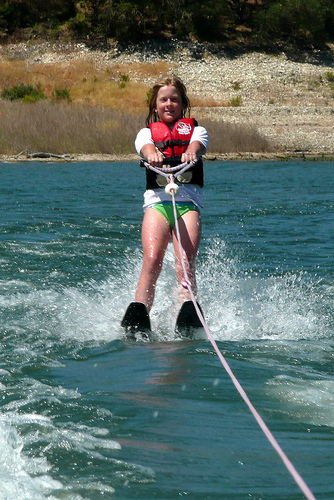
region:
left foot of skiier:
[170, 282, 222, 339]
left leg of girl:
[170, 253, 209, 315]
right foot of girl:
[108, 288, 178, 339]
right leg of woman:
[129, 244, 154, 344]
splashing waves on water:
[205, 249, 321, 337]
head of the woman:
[127, 68, 204, 119]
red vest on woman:
[140, 118, 196, 159]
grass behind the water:
[17, 95, 130, 155]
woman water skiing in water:
[98, 83, 231, 282]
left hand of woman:
[177, 143, 209, 185]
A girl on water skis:
[95, 69, 237, 351]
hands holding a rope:
[141, 146, 194, 220]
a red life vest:
[145, 118, 206, 182]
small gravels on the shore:
[210, 52, 278, 83]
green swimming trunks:
[144, 198, 199, 229]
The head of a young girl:
[152, 80, 195, 119]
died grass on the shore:
[14, 97, 114, 150]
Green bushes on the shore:
[10, 84, 72, 109]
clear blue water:
[136, 350, 234, 426]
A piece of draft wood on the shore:
[21, 150, 83, 163]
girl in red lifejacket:
[133, 75, 209, 178]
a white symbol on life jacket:
[173, 119, 193, 139]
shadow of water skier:
[112, 330, 209, 497]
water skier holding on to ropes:
[144, 77, 222, 353]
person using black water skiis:
[117, 280, 214, 343]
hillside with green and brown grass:
[5, 42, 129, 103]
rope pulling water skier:
[167, 196, 283, 448]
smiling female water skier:
[135, 68, 216, 256]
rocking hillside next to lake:
[195, 47, 320, 116]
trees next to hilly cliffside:
[47, 3, 310, 55]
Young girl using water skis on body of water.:
[120, 77, 209, 335]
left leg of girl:
[168, 248, 201, 283]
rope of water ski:
[187, 324, 297, 458]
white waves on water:
[19, 293, 123, 370]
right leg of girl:
[124, 272, 155, 326]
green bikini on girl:
[144, 194, 200, 223]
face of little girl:
[134, 74, 211, 130]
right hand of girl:
[138, 139, 162, 165]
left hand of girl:
[176, 143, 209, 179]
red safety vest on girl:
[145, 123, 207, 162]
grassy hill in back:
[40, 59, 152, 131]